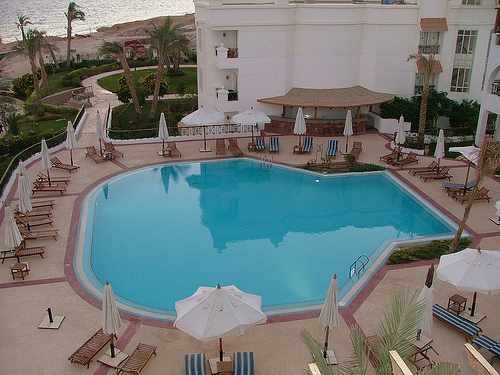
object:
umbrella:
[35, 137, 54, 173]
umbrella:
[158, 112, 170, 140]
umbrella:
[177, 105, 227, 127]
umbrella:
[343, 109, 353, 136]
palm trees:
[144, 17, 191, 120]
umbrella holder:
[38, 305, 66, 331]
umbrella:
[102, 280, 123, 336]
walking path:
[74, 61, 195, 146]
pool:
[79, 150, 465, 326]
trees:
[18, 5, 88, 113]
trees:
[149, 18, 184, 120]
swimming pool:
[80, 153, 453, 313]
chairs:
[326, 140, 339, 160]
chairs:
[302, 137, 314, 155]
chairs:
[268, 136, 279, 154]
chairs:
[254, 136, 267, 154]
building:
[176, 0, 500, 139]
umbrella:
[294, 105, 307, 135]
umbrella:
[174, 285, 267, 331]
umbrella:
[64, 120, 76, 150]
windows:
[459, 1, 484, 6]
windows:
[451, 24, 479, 56]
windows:
[451, 67, 476, 95]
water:
[1, 0, 193, 42]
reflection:
[182, 157, 453, 254]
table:
[446, 293, 466, 316]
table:
[292, 145, 301, 155]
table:
[246, 142, 256, 153]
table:
[10, 263, 28, 280]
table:
[160, 146, 172, 158]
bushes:
[11, 58, 117, 98]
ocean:
[82, 4, 133, 29]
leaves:
[373, 282, 426, 375]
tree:
[307, 284, 467, 374]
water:
[72, 151, 465, 320]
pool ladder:
[348, 253, 369, 276]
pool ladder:
[260, 155, 274, 169]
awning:
[257, 84, 397, 107]